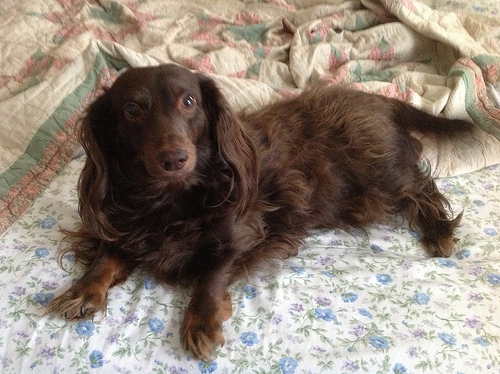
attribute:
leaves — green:
[370, 284, 405, 309]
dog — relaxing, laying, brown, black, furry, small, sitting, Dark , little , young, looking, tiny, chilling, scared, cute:
[72, 48, 474, 325]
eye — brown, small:
[172, 90, 205, 115]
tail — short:
[392, 91, 479, 150]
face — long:
[93, 67, 211, 184]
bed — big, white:
[3, 7, 499, 369]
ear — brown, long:
[198, 83, 262, 195]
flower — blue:
[88, 348, 101, 369]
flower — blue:
[241, 331, 257, 347]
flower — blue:
[279, 351, 299, 372]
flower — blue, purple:
[312, 304, 337, 325]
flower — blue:
[367, 333, 389, 350]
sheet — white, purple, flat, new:
[258, 274, 489, 371]